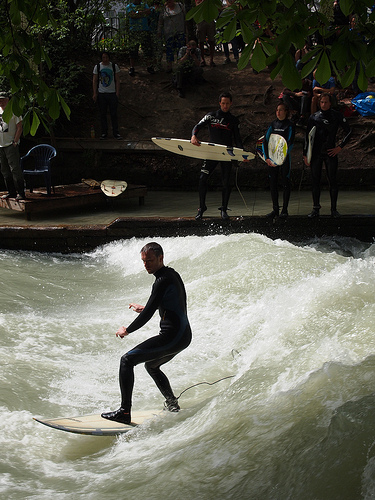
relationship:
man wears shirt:
[84, 49, 131, 139] [90, 60, 127, 96]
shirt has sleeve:
[90, 60, 127, 96] [86, 62, 104, 82]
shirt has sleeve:
[90, 60, 127, 96] [110, 64, 124, 80]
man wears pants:
[84, 49, 131, 139] [94, 90, 123, 143]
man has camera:
[172, 38, 210, 106] [184, 47, 200, 61]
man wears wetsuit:
[189, 88, 247, 222] [193, 110, 238, 211]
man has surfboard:
[189, 88, 247, 222] [146, 132, 258, 168]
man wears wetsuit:
[299, 93, 355, 222] [302, 109, 355, 210]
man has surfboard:
[299, 93, 355, 222] [305, 125, 318, 167]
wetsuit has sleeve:
[193, 110, 238, 211] [187, 110, 217, 139]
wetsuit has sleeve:
[302, 109, 355, 210] [332, 112, 356, 150]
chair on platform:
[15, 140, 63, 195] [0, 177, 151, 223]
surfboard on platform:
[97, 177, 131, 199] [0, 177, 151, 223]